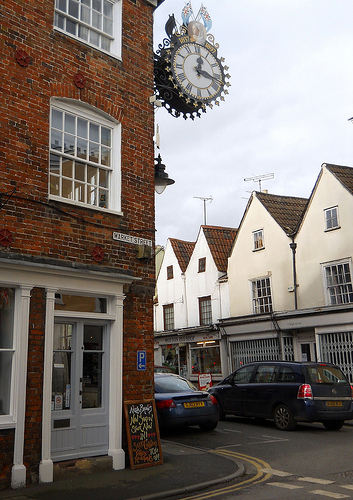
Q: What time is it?
A: 12:15.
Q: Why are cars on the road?
A: Parked.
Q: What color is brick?
A: Red.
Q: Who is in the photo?
A: Noone.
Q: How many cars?
A: 2.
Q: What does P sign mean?
A: Parking.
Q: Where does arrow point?
A: Left.